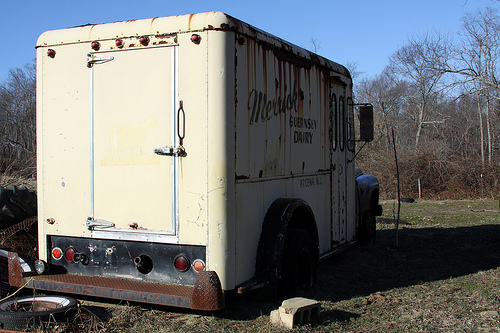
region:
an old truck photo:
[23, 6, 473, 312]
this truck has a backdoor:
[21, 27, 221, 240]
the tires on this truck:
[252, 188, 391, 281]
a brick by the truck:
[254, 279, 341, 332]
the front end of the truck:
[335, 78, 404, 246]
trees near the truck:
[342, 38, 497, 220]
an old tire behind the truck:
[5, 247, 90, 323]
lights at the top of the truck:
[27, 27, 217, 64]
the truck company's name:
[235, 60, 331, 150]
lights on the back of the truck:
[48, 231, 216, 290]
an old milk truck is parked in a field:
[6, 0, 413, 331]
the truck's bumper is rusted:
[3, 245, 228, 318]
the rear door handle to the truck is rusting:
[149, 103, 189, 170]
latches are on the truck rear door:
[83, 47, 123, 234]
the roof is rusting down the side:
[211, 9, 358, 170]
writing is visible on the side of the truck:
[237, 48, 329, 171]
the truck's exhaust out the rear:
[127, 250, 153, 277]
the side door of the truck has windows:
[326, 68, 354, 254]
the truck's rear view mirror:
[348, 90, 376, 167]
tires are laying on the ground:
[1, 235, 79, 328]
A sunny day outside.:
[0, 0, 499, 330]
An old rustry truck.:
[2, 0, 412, 330]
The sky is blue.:
[275, 1, 410, 26]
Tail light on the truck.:
[50, 245, 60, 260]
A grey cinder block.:
[265, 291, 322, 326]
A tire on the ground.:
[0, 286, 82, 328]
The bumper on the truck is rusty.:
[5, 246, 223, 311]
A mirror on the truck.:
[350, 96, 378, 146]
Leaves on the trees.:
[357, 3, 497, 198]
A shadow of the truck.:
[269, 220, 497, 329]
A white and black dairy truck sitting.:
[8, 10, 382, 314]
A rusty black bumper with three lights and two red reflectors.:
[6, 234, 221, 322]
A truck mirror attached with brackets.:
[348, 102, 373, 163]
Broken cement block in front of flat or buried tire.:
[267, 225, 319, 327]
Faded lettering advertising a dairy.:
[248, 73, 328, 188]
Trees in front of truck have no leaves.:
[3, 6, 496, 200]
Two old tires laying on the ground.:
[1, 245, 80, 330]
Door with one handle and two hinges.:
[86, 42, 186, 234]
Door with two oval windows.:
[329, 80, 349, 251]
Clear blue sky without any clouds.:
[1, 1, 496, 113]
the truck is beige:
[24, 21, 429, 308]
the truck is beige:
[12, 11, 244, 262]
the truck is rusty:
[224, 21, 368, 153]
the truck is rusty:
[214, 20, 304, 81]